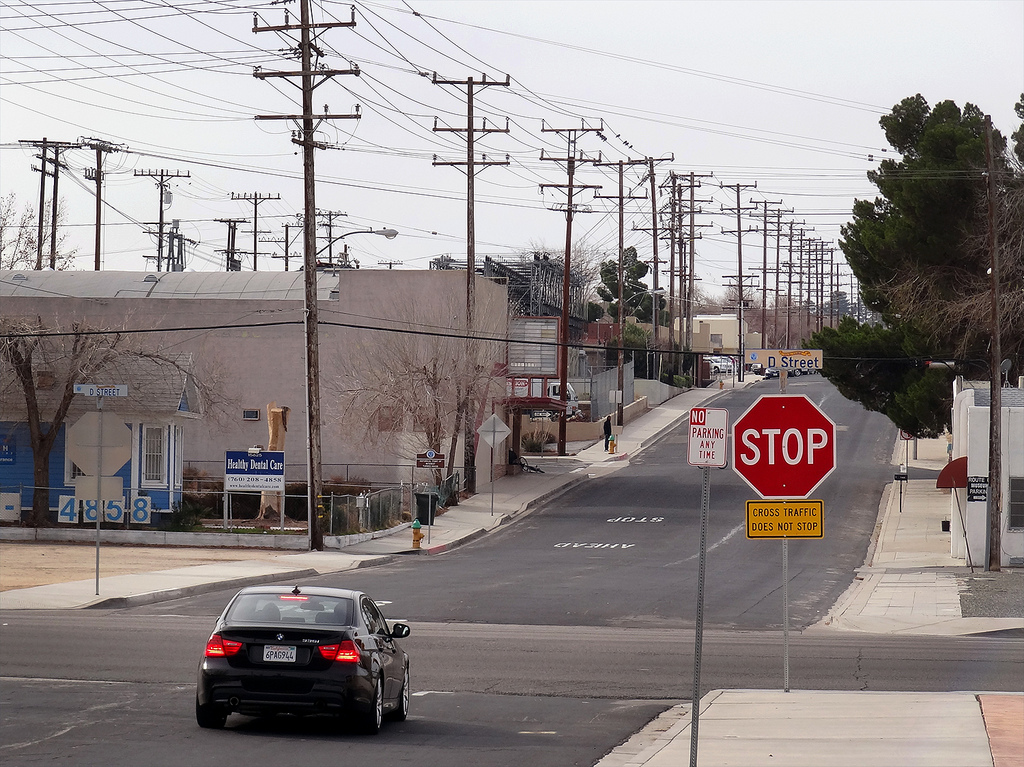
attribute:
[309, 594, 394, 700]
light — red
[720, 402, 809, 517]
sign — red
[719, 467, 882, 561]
sign — yellow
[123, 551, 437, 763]
car — black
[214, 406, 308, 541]
sign — blue, white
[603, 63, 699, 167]
sky — blue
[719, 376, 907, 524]
sign — red, white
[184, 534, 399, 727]
car — black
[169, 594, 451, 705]
lights — red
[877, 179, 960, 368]
tree — biggest, green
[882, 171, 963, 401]
leaves — dark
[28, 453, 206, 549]
numbers — blue, large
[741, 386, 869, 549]
sign — red , white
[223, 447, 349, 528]
sign — white, blue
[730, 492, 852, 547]
sign — yellow, black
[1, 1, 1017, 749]
city — industrialized 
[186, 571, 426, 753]
car — black 